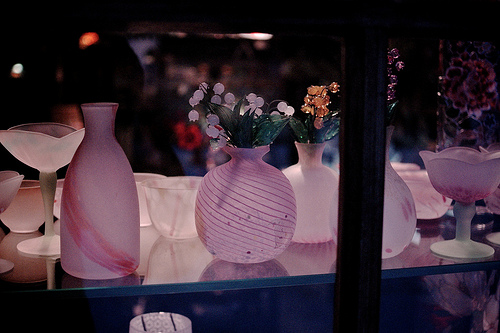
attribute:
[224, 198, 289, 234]
pattern — wavy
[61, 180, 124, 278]
color — red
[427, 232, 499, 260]
base — broad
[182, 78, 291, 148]
flowers — white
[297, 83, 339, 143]
stalks — brilliant, gold, flower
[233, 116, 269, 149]
leaves — green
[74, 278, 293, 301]
edge — blue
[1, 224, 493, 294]
top — table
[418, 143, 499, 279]
vase — pink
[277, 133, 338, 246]
vase — pink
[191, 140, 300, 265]
vase — pink, flower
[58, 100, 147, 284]
vase — pink, purple, flower, pastel, translucent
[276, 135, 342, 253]
vase — purple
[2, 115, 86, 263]
vase — pink, flower, translucent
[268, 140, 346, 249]
vase — flower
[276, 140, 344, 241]
vase — pastel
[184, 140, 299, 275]
vase — pastel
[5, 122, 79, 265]
vase — pastel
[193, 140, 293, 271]
vase — purple, translucent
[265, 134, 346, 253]
vase — translucent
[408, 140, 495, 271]
vase — purple, pastel, translucent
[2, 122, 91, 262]
vase — purple, glass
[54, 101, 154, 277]
vase — glass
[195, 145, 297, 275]
vase — glass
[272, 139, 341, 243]
vase — glass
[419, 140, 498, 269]
vase — flower, glass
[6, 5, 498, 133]
background — lit up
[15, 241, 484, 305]
shelf — dark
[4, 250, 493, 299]
shelf — glass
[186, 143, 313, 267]
vase — round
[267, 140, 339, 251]
vase — round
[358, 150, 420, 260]
vase — round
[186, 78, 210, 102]
flower — white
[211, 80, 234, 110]
flower — white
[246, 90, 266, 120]
flower — white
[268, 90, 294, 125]
flower — white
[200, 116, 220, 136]
flower — white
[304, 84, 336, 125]
flowers — orange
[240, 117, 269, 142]
leaves — green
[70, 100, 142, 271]
vase — pink, white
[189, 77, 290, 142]
flowers — white, little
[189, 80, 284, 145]
flowers — white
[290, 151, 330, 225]
vase — little, orange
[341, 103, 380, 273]
pole — brown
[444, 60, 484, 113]
flower — big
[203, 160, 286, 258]
vase — white, round, pink, striped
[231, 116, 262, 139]
stems — green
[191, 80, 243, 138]
flowers — white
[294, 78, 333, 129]
flowers — yellow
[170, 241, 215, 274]
surface — reflective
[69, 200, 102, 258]
stripe — red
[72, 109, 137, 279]
vase — tall, pink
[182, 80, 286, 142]
flowers — White